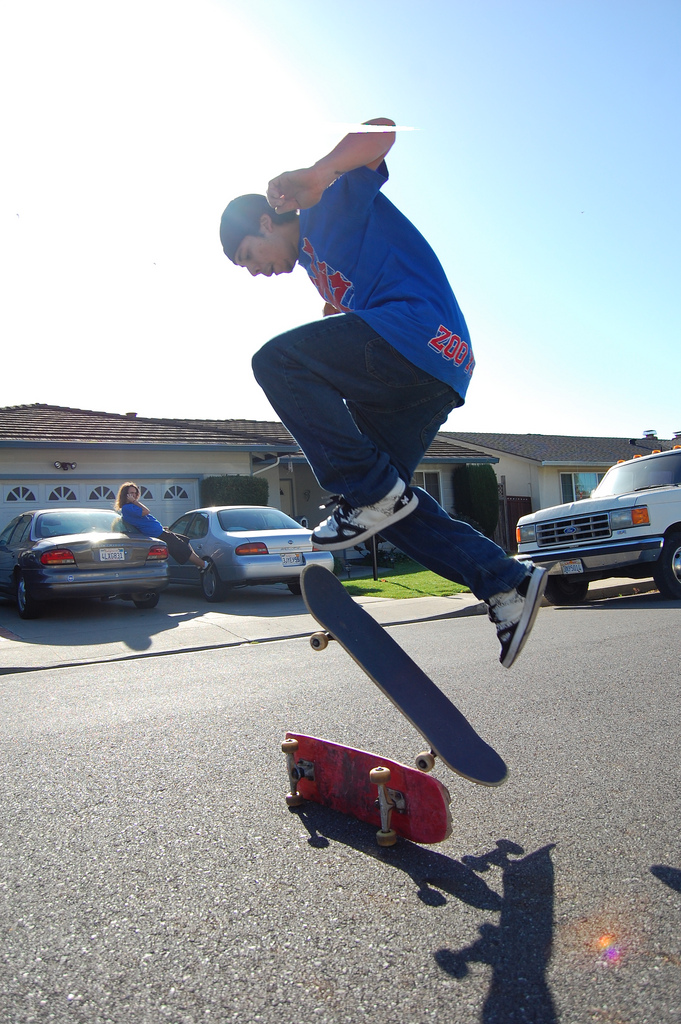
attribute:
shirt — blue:
[262, 175, 519, 405]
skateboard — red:
[281, 734, 451, 847]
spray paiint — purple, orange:
[548, 883, 661, 987]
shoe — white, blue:
[489, 554, 558, 680]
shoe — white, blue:
[293, 487, 419, 566]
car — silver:
[161, 502, 324, 610]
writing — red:
[290, 232, 356, 312]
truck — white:
[500, 435, 678, 603]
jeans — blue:
[247, 307, 511, 597]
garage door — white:
[0, 470, 208, 583]